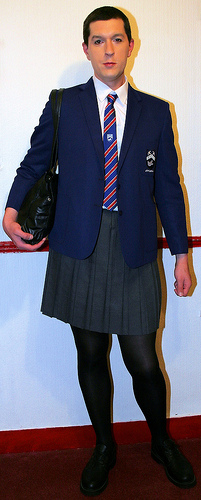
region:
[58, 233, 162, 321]
The man is wearing a skirt.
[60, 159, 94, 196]
The jacket is blue.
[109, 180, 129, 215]
The buttons are black.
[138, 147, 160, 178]
Emblem on the jacket.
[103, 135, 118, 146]
Emblem on the tie.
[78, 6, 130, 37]
The man has dark hair.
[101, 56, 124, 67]
The man is wearing lipstick.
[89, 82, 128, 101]
The shirt is white.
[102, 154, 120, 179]
The tie is red and blue.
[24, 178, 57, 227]
The purse is black.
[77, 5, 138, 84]
a man wearing make-up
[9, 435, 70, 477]
a red floor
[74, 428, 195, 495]
a pair of black dress shoes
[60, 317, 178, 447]
a man wearing black tights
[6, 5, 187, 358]
a man wearing a school girls skirt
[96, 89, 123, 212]
a red and blue tie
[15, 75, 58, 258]
a black leather purse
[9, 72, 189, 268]
a blue sports coat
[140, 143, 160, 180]
a school emblem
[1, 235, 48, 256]
red crown molding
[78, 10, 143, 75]
face of the person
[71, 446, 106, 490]
shoe of the person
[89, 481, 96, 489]
light on the shoe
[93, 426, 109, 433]
black socks on the shoe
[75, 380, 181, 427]
legs of the person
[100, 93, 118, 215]
a tie wearing by person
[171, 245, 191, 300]
hand of the person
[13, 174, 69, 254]
a person holding the bag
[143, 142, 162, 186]
a logo on the shirt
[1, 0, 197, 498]
a man wearing a skirt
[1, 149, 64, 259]
hand holding a black purse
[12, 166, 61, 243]
the purse is black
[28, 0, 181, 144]
person has short hair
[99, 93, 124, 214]
a blue tie with red stripes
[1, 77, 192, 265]
a blue jacket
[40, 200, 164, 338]
a gray skirt under a blue jacket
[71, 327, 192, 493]
black long socks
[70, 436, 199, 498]
a pair of black shoes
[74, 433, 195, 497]
black men's dress shoes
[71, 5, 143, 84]
a man with make-up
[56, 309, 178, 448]
black tights on a man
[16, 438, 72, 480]
a red floor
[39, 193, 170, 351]
a grey school girl's skirt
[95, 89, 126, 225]
a red and blue striped tie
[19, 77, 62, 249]
a black leather purse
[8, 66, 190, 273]
a blue sports coat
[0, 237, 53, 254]
red crown molding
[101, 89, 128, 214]
a blue tie with stripes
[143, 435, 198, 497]
an all black shoe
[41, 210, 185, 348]
a grey skirt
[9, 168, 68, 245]
a black purse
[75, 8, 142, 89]
a mans face with makeup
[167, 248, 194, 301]
a mans hand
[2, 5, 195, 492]
a man in a skirt and a blue blazer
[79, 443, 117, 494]
black shoes on a man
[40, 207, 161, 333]
a gray pleated skirt on a man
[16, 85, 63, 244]
a black leather purse on a man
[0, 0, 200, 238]
a white wall behind a man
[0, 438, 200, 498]
a dark red carpet on the floor